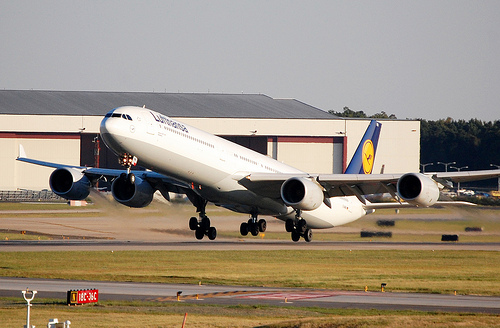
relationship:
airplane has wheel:
[130, 117, 236, 162] [201, 220, 209, 228]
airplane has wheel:
[130, 117, 236, 162] [190, 215, 196, 225]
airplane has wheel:
[130, 117, 236, 162] [210, 233, 215, 237]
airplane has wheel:
[130, 117, 236, 162] [197, 235, 202, 240]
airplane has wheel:
[130, 117, 236, 162] [299, 225, 306, 230]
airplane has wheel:
[130, 117, 236, 162] [285, 220, 291, 228]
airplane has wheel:
[130, 117, 236, 162] [307, 233, 312, 238]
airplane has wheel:
[130, 117, 236, 162] [292, 237, 296, 242]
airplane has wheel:
[130, 117, 236, 162] [252, 230, 257, 234]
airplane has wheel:
[130, 117, 236, 162] [241, 224, 246, 234]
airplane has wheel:
[130, 117, 236, 162] [249, 219, 252, 224]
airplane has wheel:
[130, 117, 236, 162] [262, 221, 265, 223]